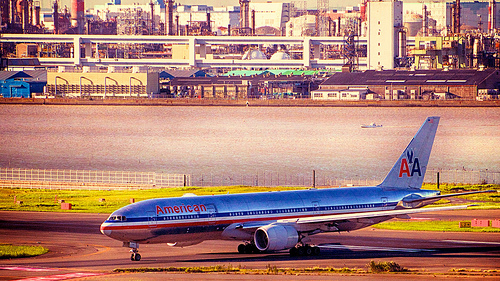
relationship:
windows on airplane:
[160, 210, 307, 217] [92, 107, 500, 273]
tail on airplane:
[385, 114, 442, 192] [92, 107, 500, 273]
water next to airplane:
[2, 103, 499, 181] [92, 107, 500, 273]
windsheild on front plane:
[105, 214, 126, 225] [92, 107, 500, 273]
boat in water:
[358, 118, 384, 130] [2, 103, 499, 181]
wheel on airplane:
[129, 248, 143, 262] [92, 107, 500, 273]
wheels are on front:
[129, 248, 145, 263] [100, 188, 156, 280]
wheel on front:
[129, 248, 145, 263] [100, 188, 156, 280]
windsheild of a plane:
[105, 214, 126, 225] [92, 107, 500, 273]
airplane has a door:
[92, 107, 500, 273] [146, 207, 160, 231]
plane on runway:
[92, 107, 500, 273] [7, 207, 500, 271]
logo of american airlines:
[399, 151, 424, 181] [92, 107, 500, 273]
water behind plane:
[2, 103, 499, 181] [92, 107, 500, 273]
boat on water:
[358, 118, 384, 130] [2, 103, 499, 181]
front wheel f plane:
[129, 248, 145, 263] [92, 107, 500, 273]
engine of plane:
[250, 220, 299, 253] [92, 107, 500, 273]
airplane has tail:
[92, 107, 500, 273] [385, 114, 442, 192]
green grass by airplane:
[7, 183, 135, 208] [92, 107, 500, 273]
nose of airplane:
[97, 202, 137, 245] [92, 107, 500, 273]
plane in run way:
[92, 107, 500, 273] [7, 207, 500, 271]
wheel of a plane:
[129, 248, 145, 263] [92, 107, 500, 273]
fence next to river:
[2, 168, 191, 191] [2, 103, 499, 181]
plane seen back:
[92, 107, 500, 273] [382, 114, 499, 223]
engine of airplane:
[250, 220, 299, 253] [92, 107, 500, 273]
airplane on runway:
[92, 107, 500, 273] [7, 207, 500, 271]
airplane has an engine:
[92, 107, 500, 273] [250, 220, 299, 253]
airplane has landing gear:
[92, 107, 500, 273] [125, 239, 144, 262]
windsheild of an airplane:
[105, 214, 126, 225] [92, 107, 500, 273]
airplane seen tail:
[92, 107, 500, 273] [385, 114, 442, 192]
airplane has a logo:
[92, 107, 500, 273] [399, 151, 424, 181]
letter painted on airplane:
[153, 200, 210, 216] [92, 107, 500, 273]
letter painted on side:
[153, 200, 210, 216] [137, 195, 315, 227]